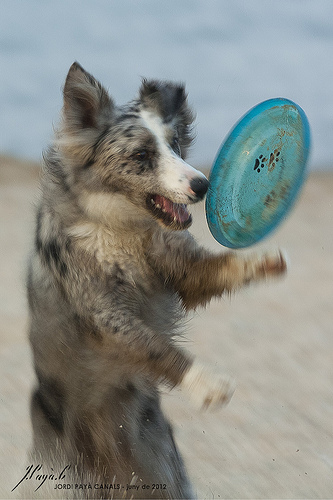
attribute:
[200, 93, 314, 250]
frisbee — blue, airborne, dirty, sandy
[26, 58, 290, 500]
dog — australian shepherd, jumping, gray., fuzzy, brown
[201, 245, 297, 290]
paw — white, blurry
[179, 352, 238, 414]
paw — white, blurry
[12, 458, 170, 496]
copyright — black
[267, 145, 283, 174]
paw — black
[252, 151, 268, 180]
paw — black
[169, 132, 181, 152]
eye — dark, black, amber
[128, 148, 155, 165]
eye — dark, black, amber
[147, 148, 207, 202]
snout — white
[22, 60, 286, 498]
fur — grey, black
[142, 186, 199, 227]
mouth — open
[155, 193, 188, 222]
tongue — pink, orange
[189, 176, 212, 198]
nose — black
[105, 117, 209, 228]
face — white, black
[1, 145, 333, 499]
beach — brown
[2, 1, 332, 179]
water — blue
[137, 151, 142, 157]
pupil — black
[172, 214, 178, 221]
tooth — white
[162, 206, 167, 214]
tooth — white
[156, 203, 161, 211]
tooth — white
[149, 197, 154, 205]
tooth — white